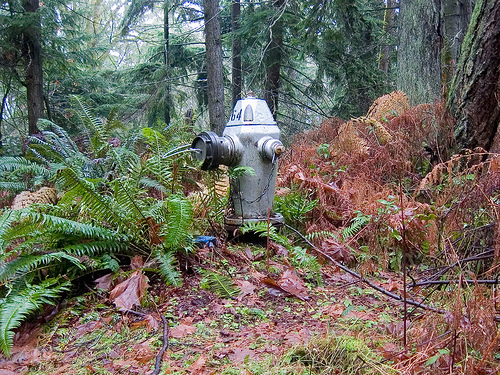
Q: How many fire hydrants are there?
A: One.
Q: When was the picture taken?
A: Daytime.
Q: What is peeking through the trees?
A: Sky.